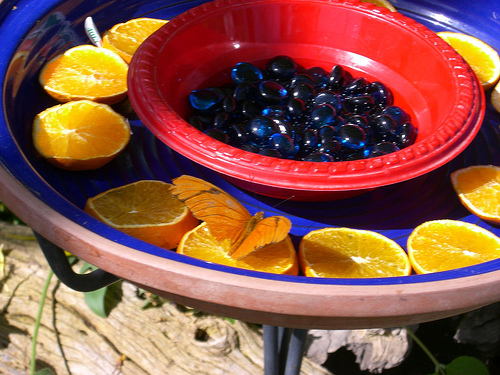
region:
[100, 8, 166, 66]
orange slice on plate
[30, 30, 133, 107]
orange slice on plate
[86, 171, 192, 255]
orange slice on plate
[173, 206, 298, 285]
orange slice on plate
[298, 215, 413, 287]
orange slice on plate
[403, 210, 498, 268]
orange slice on plate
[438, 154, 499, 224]
orange slice on plate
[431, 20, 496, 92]
orange slice on plate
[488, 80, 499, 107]
orange slice on plate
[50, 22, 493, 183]
a plete is on a tray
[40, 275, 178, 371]
a log of tree under the stand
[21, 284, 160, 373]
th log is brown in color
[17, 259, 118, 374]
plants is seen on the log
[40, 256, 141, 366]
plant is green in color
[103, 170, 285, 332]
the trayis blue in color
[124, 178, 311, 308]
the tray is aranged with slices of oranges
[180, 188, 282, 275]
a buterfly is on the oranges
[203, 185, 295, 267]
th buterfly is ornge o= in color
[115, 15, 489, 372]
the bowl has fruit in it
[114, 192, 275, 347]
the bowl has oranges in it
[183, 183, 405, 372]
a butterfly is on the orange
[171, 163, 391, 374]
the butterfly is orange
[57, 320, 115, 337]
the wood is distressed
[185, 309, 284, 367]
the wood has a hole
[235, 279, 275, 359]
the bowl is propped on metal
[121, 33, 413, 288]
the bowl is red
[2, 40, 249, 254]
the bowl is blue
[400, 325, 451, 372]
leaves are below the bowl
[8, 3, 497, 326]
a blue of fruit and glass pebbles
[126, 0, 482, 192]
a red bowl of blue glass pebbles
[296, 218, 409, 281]
a half of an orange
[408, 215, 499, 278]
a half of an orange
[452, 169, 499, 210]
a half of an orange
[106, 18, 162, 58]
a half of an orange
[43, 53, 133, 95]
a half of an orange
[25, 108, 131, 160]
a half of an orange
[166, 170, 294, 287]
a moth on a sliced orange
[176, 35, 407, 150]
blue jewels in a bowl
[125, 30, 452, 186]
red bowl on a platter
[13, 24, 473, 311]
inside of platter is blue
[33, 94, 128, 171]
half of orange on platter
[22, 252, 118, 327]
green leaves on the ground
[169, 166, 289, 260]
orange butterfly on fruit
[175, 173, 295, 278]
butterfly on a orange slice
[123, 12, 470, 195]
bowl is red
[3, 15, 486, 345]
outer side of platter is brown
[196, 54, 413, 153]
blue gems are glass